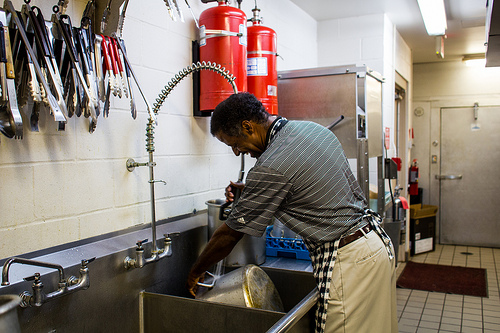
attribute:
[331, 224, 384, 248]
belt — brown , leather 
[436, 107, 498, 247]
door — stainless steel, heavy, gray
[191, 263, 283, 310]
pot — large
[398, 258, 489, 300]
rug — dark brown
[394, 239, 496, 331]
floor — tile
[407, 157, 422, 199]
fire extinguisher — red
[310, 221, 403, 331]
pants — khaki, tan 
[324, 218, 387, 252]
belt — brown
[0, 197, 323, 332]
sink — large, metal, gray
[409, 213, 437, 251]
box — black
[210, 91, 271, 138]
hair — black, gray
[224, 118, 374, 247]
shirt — gray, striped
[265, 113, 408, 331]
apron — checkered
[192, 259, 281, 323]
pot — huge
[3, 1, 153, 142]
utensils — kitchen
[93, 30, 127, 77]
handles — red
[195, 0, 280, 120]
tanks — red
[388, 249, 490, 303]
mat — brown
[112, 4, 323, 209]
wall — white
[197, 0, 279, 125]
fire extinquishers — red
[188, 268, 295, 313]
pot — stainless steel, large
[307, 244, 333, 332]
apron — checkered, white, black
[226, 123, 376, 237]
shirt — gray, white, short sleeved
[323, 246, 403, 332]
pants — khaki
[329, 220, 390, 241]
belt — brown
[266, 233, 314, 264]
dish rack — blue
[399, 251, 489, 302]
rug — red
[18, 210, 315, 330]
sink — stainless steel, stainless , steel , gray